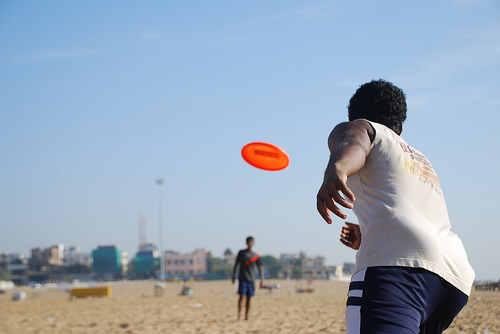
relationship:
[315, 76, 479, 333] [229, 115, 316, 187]
man tossing frisbee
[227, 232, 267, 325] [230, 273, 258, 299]
boy wearing shorts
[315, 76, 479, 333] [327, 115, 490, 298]
man wearing grey shirt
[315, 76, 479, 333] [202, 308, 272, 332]
man on sand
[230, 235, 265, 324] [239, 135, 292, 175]
boy waiting on frisbee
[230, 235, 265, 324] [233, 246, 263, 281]
boy with shirt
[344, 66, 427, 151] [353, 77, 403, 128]
back of head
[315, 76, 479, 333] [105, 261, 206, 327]
man lunging in sand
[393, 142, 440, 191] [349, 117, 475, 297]
letters back of grey shirt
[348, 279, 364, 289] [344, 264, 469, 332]
stripe on shorts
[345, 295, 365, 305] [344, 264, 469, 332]
stripe on shorts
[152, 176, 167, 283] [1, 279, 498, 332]
pole in sand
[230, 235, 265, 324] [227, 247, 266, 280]
boy wearing grey shirt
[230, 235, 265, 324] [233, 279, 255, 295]
boy wearing blue shorts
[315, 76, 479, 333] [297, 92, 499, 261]
man has shirt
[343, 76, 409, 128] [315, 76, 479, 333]
hair on man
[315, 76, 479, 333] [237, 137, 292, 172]
man catching frisbee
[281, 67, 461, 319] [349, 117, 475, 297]
man wearing a grey shirt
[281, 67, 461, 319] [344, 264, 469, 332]
man wearing a shorts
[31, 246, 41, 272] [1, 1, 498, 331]
building in back ground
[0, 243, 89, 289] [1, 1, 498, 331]
building in back ground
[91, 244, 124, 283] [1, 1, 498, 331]
blue building in back ground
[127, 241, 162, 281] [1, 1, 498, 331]
blue building in back ground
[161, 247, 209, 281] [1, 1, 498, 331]
building in back ground